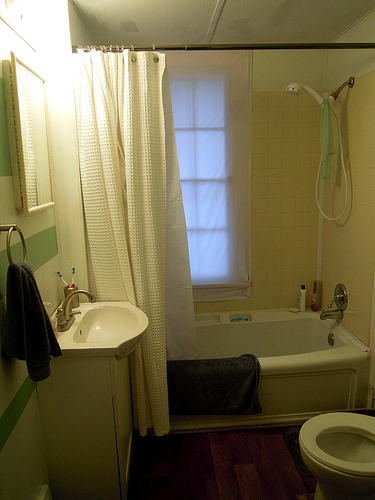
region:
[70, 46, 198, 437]
A white shower curtain.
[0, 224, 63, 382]
A black hand towel hanging from a ring.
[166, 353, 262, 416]
A black bath towel draped over the tub.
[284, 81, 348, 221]
A shower head with a hose.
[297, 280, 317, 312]
Two bottles of shampoo.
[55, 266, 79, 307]
Two toothebrushes in a silver holder.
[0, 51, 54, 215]
A mirrored medicine cabinet.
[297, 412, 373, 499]
A white toilet with the seat down.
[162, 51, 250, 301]
A white covering is over the window.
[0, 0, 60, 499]
A wall is painted with green stripes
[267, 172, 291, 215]
part of a wall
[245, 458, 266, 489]
part of a floor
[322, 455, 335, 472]
edge of a lid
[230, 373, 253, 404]
part of a cloth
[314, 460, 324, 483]
part of a toilet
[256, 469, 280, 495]
part of a floor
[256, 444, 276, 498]
part of a floor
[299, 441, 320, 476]
part of a toilet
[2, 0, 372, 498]
a scene of a bathroom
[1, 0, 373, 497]
a scene inside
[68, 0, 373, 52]
a white ceiling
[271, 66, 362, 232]
a shower nozzle head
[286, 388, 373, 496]
a white toilet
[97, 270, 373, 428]
a bathtub with soap and bottles on the outer area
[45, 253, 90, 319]
two toothbrushes in a silver can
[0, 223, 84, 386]
a towel on the rack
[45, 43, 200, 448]
a white shower curtain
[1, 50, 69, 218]
a medicine cabinet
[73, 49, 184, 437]
A long white shower curtain.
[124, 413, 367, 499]
Hardwood floors.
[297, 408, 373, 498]
A white toilet.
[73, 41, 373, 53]
A silver shower curtain rod.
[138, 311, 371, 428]
A white bathtub.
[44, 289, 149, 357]
A white sink.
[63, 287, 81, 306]
A silver toothbrush holder.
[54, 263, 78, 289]
Two toothbrushes.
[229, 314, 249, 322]
A blue handle of a razor.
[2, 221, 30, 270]
A round silver towel rack.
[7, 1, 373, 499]
the scene is in a bathroom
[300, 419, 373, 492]
a white toilet seat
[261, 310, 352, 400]
a white bathtub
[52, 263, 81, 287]
toothbrushes are placed inside a glass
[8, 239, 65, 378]
a towel hanged on a ring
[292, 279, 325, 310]
appling oil on the bathtub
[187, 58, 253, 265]
curtains are drawn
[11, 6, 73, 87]
the light is shining brightly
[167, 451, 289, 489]
brown wooden planks are making the floor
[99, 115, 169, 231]
a white woolen curtain